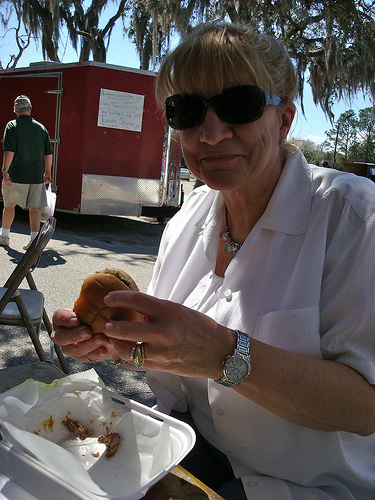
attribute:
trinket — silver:
[214, 232, 230, 238]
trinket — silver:
[223, 238, 235, 255]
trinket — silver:
[223, 236, 243, 252]